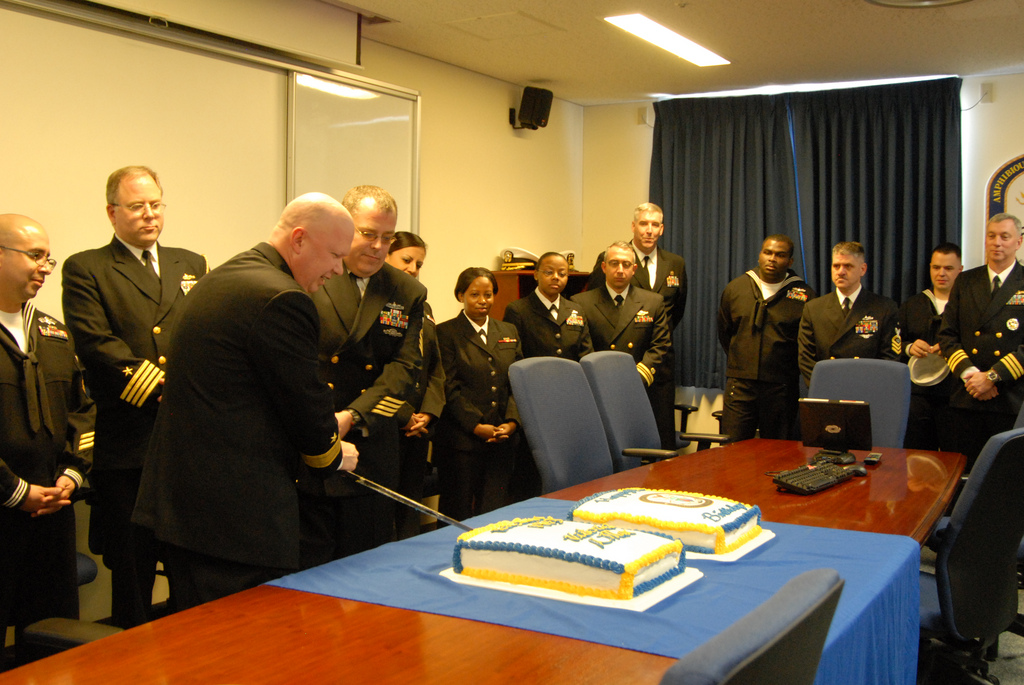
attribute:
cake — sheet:
[454, 517, 702, 606]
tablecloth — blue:
[4, 440, 968, 682]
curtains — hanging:
[642, 92, 971, 397]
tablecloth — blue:
[269, 497, 918, 684]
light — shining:
[596, 13, 729, 77]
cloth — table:
[295, 479, 944, 680]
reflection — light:
[283, 73, 426, 251]